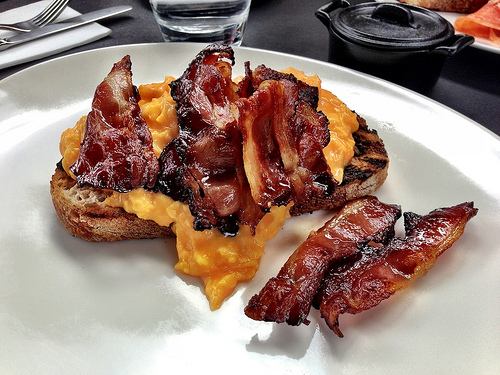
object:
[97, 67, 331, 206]
bacon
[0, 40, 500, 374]
plate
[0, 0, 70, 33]
fork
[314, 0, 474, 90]
pot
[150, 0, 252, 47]
glass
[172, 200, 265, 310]
cheese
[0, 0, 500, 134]
table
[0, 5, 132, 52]
knife